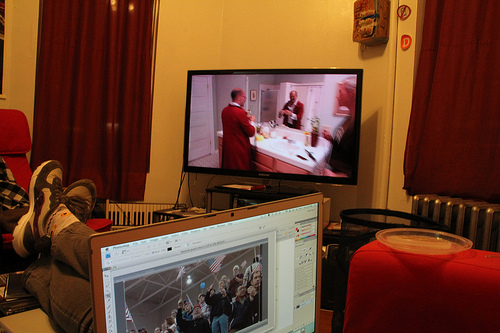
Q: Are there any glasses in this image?
A: No, there are no glasses.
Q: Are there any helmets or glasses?
A: No, there are no glasses or helmets.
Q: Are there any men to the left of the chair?
A: No, the man is to the right of the chair.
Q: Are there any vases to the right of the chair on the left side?
A: No, there is a man to the right of the chair.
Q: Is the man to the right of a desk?
A: No, the man is to the right of the chair.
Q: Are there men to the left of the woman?
A: Yes, there is a man to the left of the woman.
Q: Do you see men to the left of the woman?
A: Yes, there is a man to the left of the woman.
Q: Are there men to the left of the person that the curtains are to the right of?
A: Yes, there is a man to the left of the woman.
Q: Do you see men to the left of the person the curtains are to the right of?
A: Yes, there is a man to the left of the woman.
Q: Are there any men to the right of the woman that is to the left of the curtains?
A: No, the man is to the left of the woman.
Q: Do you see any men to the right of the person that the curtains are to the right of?
A: No, the man is to the left of the woman.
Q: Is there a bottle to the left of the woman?
A: No, there is a man to the left of the woman.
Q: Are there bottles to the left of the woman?
A: No, there is a man to the left of the woman.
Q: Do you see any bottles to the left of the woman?
A: No, there is a man to the left of the woman.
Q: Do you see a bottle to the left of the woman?
A: No, there is a man to the left of the woman.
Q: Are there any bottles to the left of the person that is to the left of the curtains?
A: No, there is a man to the left of the woman.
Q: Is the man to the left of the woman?
A: Yes, the man is to the left of the woman.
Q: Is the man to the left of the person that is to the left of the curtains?
A: Yes, the man is to the left of the woman.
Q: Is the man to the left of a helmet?
A: No, the man is to the left of the woman.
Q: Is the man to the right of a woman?
A: No, the man is to the left of a woman.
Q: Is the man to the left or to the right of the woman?
A: The man is to the left of the woman.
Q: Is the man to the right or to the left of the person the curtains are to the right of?
A: The man is to the left of the woman.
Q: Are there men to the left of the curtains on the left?
A: No, the man is to the right of the curtains.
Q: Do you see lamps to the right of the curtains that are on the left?
A: No, there is a man to the right of the curtains.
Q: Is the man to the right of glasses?
A: No, the man is to the right of the curtains.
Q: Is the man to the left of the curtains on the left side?
A: No, the man is to the right of the curtains.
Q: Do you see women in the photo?
A: Yes, there is a woman.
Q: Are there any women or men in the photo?
A: Yes, there is a woman.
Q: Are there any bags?
A: No, there are no bags.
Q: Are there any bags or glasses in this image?
A: No, there are no bags or glasses.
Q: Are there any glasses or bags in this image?
A: No, there are no bags or glasses.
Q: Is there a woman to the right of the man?
A: Yes, there is a woman to the right of the man.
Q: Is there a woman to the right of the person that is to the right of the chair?
A: Yes, there is a woman to the right of the man.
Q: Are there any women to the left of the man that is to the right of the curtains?
A: No, the woman is to the right of the man.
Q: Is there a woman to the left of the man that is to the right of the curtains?
A: No, the woman is to the right of the man.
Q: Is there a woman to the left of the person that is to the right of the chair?
A: No, the woman is to the right of the man.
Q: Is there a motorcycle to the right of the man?
A: No, there is a woman to the right of the man.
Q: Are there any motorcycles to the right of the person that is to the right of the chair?
A: No, there is a woman to the right of the man.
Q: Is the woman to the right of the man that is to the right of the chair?
A: Yes, the woman is to the right of the man.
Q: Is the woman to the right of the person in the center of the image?
A: Yes, the woman is to the right of the man.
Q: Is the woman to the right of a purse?
A: No, the woman is to the right of the man.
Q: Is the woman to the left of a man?
A: No, the woman is to the right of a man.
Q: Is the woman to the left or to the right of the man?
A: The woman is to the right of the man.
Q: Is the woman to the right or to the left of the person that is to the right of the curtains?
A: The woman is to the right of the man.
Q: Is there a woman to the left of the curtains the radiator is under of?
A: Yes, there is a woman to the left of the curtains.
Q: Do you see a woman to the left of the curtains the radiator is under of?
A: Yes, there is a woman to the left of the curtains.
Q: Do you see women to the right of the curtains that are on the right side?
A: No, the woman is to the left of the curtains.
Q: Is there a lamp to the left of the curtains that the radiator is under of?
A: No, there is a woman to the left of the curtains.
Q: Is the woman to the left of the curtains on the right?
A: Yes, the woman is to the left of the curtains.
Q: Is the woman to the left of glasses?
A: No, the woman is to the left of the curtains.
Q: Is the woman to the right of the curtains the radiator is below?
A: No, the woman is to the left of the curtains.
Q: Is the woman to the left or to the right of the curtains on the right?
A: The woman is to the left of the curtains.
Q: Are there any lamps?
A: No, there are no lamps.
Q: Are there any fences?
A: No, there are no fences.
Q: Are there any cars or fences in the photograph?
A: No, there are no fences or cars.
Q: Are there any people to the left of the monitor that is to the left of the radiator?
A: Yes, there is a person to the left of the monitor.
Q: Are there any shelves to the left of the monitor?
A: No, there is a person to the left of the monitor.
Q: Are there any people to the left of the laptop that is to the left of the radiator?
A: Yes, there is a person to the left of the laptop.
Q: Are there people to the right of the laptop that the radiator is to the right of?
A: No, the person is to the left of the laptop.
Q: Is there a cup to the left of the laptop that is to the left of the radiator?
A: No, there is a person to the left of the laptop.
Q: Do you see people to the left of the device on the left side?
A: Yes, there is a person to the left of the keyboard.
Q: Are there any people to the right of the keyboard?
A: No, the person is to the left of the keyboard.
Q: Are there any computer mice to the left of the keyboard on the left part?
A: No, there is a person to the left of the keyboard.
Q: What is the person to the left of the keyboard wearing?
A: The person is wearing sneakers.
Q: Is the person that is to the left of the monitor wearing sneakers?
A: Yes, the person is wearing sneakers.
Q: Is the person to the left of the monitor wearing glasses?
A: No, the person is wearing sneakers.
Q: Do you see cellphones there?
A: No, there are no cellphones.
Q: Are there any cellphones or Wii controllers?
A: No, there are no cellphones or Wii controllers.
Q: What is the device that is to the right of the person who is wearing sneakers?
A: The device is a monitor.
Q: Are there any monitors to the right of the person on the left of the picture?
A: Yes, there is a monitor to the right of the person.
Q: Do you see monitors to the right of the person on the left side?
A: Yes, there is a monitor to the right of the person.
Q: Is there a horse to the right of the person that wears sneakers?
A: No, there is a monitor to the right of the person.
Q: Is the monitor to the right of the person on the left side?
A: Yes, the monitor is to the right of the person.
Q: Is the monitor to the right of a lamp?
A: No, the monitor is to the right of the person.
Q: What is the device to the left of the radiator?
A: The device is a monitor.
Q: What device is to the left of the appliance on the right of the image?
A: The device is a monitor.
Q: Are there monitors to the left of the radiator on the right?
A: Yes, there is a monitor to the left of the radiator.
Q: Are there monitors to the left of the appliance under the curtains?
A: Yes, there is a monitor to the left of the radiator.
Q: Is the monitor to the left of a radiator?
A: Yes, the monitor is to the left of a radiator.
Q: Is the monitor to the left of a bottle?
A: No, the monitor is to the left of a radiator.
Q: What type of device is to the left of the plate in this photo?
A: The device is a monitor.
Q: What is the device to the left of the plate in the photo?
A: The device is a monitor.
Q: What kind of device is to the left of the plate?
A: The device is a monitor.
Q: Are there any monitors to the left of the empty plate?
A: Yes, there is a monitor to the left of the plate.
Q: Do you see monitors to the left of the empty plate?
A: Yes, there is a monitor to the left of the plate.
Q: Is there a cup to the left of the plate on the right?
A: No, there is a monitor to the left of the plate.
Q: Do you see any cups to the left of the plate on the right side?
A: No, there is a monitor to the left of the plate.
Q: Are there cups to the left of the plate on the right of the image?
A: No, there is a monitor to the left of the plate.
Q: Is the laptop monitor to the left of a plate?
A: Yes, the monitor is to the left of a plate.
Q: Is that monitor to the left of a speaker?
A: No, the monitor is to the left of a plate.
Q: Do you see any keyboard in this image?
A: Yes, there is a keyboard.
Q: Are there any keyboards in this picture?
A: Yes, there is a keyboard.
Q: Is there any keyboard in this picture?
A: Yes, there is a keyboard.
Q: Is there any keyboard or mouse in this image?
A: Yes, there is a keyboard.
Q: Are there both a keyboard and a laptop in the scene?
A: Yes, there are both a keyboard and a laptop.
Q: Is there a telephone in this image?
A: No, there are no phones.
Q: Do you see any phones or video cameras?
A: No, there are no phones or video cameras.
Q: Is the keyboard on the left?
A: Yes, the keyboard is on the left of the image.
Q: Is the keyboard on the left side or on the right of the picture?
A: The keyboard is on the left of the image.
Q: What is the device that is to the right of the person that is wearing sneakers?
A: The device is a keyboard.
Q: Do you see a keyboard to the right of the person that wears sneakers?
A: Yes, there is a keyboard to the right of the person.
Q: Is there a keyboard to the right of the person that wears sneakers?
A: Yes, there is a keyboard to the right of the person.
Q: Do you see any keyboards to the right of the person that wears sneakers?
A: Yes, there is a keyboard to the right of the person.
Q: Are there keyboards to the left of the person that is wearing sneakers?
A: No, the keyboard is to the right of the person.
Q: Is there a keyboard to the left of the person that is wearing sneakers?
A: No, the keyboard is to the right of the person.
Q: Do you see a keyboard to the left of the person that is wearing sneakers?
A: No, the keyboard is to the right of the person.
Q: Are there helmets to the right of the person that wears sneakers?
A: No, there is a keyboard to the right of the person.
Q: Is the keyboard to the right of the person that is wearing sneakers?
A: Yes, the keyboard is to the right of the person.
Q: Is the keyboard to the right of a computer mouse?
A: No, the keyboard is to the right of the person.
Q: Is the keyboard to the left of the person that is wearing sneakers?
A: No, the keyboard is to the right of the person.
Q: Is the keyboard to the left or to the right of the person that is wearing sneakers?
A: The keyboard is to the right of the person.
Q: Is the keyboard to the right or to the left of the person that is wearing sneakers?
A: The keyboard is to the right of the person.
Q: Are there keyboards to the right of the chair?
A: Yes, there is a keyboard to the right of the chair.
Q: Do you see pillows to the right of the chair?
A: No, there is a keyboard to the right of the chair.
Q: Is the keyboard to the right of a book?
A: No, the keyboard is to the right of a chair.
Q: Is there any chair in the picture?
A: Yes, there is a chair.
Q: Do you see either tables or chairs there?
A: Yes, there is a chair.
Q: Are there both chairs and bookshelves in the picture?
A: No, there is a chair but no bookshelves.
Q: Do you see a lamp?
A: No, there are no lamps.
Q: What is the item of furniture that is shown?
A: The piece of furniture is a chair.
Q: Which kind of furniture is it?
A: The piece of furniture is a chair.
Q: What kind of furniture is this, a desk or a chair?
A: That is a chair.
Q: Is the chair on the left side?
A: Yes, the chair is on the left of the image.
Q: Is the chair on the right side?
A: No, the chair is on the left of the image.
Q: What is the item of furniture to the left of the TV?
A: The piece of furniture is a chair.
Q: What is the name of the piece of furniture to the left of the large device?
A: The piece of furniture is a chair.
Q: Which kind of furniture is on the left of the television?
A: The piece of furniture is a chair.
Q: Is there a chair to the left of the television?
A: Yes, there is a chair to the left of the television.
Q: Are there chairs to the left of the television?
A: Yes, there is a chair to the left of the television.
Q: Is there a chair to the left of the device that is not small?
A: Yes, there is a chair to the left of the television.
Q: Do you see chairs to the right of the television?
A: No, the chair is to the left of the television.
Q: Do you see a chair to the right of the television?
A: No, the chair is to the left of the television.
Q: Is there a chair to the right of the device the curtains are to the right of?
A: No, the chair is to the left of the television.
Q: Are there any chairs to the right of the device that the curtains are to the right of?
A: No, the chair is to the left of the television.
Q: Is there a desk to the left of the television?
A: No, there is a chair to the left of the television.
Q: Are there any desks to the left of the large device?
A: No, there is a chair to the left of the television.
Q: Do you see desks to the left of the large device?
A: No, there is a chair to the left of the television.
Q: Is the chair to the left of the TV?
A: Yes, the chair is to the left of the TV.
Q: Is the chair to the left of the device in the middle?
A: Yes, the chair is to the left of the TV.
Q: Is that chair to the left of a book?
A: No, the chair is to the left of the TV.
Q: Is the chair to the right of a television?
A: No, the chair is to the left of a television.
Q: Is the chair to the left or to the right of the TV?
A: The chair is to the left of the TV.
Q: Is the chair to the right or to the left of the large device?
A: The chair is to the left of the TV.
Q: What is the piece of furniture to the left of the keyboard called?
A: The piece of furniture is a chair.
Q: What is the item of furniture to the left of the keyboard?
A: The piece of furniture is a chair.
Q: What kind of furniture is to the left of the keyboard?
A: The piece of furniture is a chair.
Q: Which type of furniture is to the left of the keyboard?
A: The piece of furniture is a chair.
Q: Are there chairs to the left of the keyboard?
A: Yes, there is a chair to the left of the keyboard.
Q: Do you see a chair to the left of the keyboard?
A: Yes, there is a chair to the left of the keyboard.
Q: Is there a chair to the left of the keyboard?
A: Yes, there is a chair to the left of the keyboard.